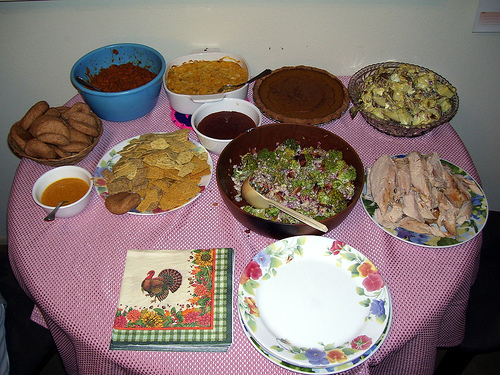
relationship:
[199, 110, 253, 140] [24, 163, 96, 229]
liquid in bowl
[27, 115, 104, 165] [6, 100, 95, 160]
basket filled with bread rolls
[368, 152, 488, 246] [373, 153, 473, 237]
plate filled with meat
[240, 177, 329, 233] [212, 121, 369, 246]
spoon in a bowl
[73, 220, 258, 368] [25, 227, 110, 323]
napkins on table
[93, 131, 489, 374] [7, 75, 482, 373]
plate on table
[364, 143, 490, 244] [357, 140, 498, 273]
meat on plate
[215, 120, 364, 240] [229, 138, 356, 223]
bowl of salad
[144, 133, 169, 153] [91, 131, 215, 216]
cracker on plate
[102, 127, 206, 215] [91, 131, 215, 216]
cracker on plate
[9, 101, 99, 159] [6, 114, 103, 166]
roll on bowl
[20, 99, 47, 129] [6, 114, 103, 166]
roll on bowl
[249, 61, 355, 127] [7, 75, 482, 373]
pie on table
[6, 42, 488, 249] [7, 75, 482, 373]
food on table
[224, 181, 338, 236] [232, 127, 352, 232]
spoon in salad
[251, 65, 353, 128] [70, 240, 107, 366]
pie on a table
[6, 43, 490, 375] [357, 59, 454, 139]
bowl of vegetables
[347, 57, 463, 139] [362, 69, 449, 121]
dish full of food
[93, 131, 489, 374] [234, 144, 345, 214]
plate with flowers